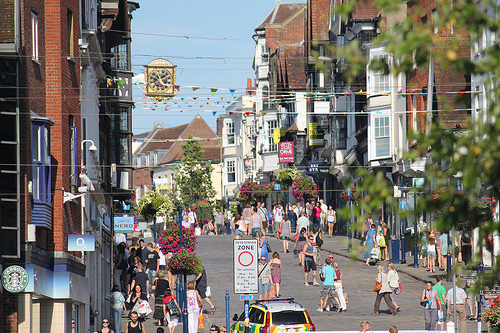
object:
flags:
[191, 86, 201, 92]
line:
[310, 107, 441, 116]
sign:
[230, 236, 261, 295]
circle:
[237, 250, 255, 267]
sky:
[133, 0, 252, 121]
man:
[301, 234, 320, 288]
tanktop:
[304, 242, 315, 261]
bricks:
[45, 14, 53, 17]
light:
[80, 139, 99, 152]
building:
[0, 0, 139, 333]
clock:
[141, 57, 179, 102]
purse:
[373, 272, 383, 291]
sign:
[2, 264, 30, 294]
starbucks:
[0, 264, 31, 294]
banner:
[277, 141, 295, 163]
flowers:
[294, 192, 298, 195]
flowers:
[163, 245, 166, 248]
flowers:
[255, 187, 259, 189]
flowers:
[185, 261, 188, 263]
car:
[231, 296, 316, 333]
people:
[315, 253, 348, 315]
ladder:
[0, 54, 21, 259]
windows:
[373, 137, 389, 158]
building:
[359, 0, 469, 178]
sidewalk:
[321, 234, 366, 249]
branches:
[465, 139, 500, 168]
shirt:
[144, 251, 160, 271]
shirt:
[318, 264, 339, 287]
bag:
[165, 299, 180, 316]